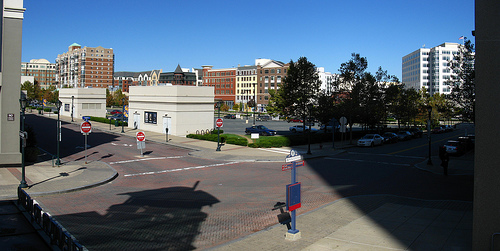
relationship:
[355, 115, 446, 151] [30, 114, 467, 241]
cars parked on side of road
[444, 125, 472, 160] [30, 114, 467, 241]
cars parked on side of road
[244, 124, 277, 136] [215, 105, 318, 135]
cars parked in parking lot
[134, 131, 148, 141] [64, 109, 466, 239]
sign on street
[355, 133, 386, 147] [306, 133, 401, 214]
cars parked along street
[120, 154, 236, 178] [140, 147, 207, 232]
lines on street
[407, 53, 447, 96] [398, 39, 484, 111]
windows on offfice building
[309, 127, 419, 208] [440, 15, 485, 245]
shadow of building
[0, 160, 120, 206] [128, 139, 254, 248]
corner of intersection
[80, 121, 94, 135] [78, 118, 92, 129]
sign with circle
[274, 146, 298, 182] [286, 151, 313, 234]
sign on pole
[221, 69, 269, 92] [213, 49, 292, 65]
windows on building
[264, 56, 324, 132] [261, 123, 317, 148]
tree growing in grass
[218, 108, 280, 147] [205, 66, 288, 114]
parking lot next to buildings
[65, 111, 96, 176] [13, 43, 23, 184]
sign next to building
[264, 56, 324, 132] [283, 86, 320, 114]
tree has leaves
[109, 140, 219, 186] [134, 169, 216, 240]
lines painted on road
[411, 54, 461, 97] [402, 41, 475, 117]
windows on offfice building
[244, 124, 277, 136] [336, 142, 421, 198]
cars parked in road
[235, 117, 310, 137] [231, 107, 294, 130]
cars parked in parking lot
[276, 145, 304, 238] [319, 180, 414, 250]
pole on sidewalk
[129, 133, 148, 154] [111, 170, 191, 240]
sign on road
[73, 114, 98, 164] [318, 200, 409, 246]
sign on sidewalk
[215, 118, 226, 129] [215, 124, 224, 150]
sign attached to pole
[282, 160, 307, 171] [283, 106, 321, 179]
sign to pole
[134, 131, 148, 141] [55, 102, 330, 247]
sign on road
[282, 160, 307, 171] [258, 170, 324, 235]
sign on pole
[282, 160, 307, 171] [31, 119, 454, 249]
sign next to street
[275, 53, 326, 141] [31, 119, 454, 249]
tree next to street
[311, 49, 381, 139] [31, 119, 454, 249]
tree next to street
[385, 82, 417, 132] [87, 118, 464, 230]
tree next to street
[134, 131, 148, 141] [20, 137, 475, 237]
sign next to street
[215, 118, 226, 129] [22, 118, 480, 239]
sign next to street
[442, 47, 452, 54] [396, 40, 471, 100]
window on building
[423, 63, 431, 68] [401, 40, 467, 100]
window on building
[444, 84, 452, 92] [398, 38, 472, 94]
window on building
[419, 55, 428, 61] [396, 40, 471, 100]
window on building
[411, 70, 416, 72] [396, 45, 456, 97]
window on building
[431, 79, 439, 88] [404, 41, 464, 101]
window on building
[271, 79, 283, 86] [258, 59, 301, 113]
window on building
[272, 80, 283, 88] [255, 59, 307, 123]
window on building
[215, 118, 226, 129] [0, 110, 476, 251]
sign on road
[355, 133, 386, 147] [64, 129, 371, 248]
cars parked on side of street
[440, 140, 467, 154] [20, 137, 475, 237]
cars parked on side of street